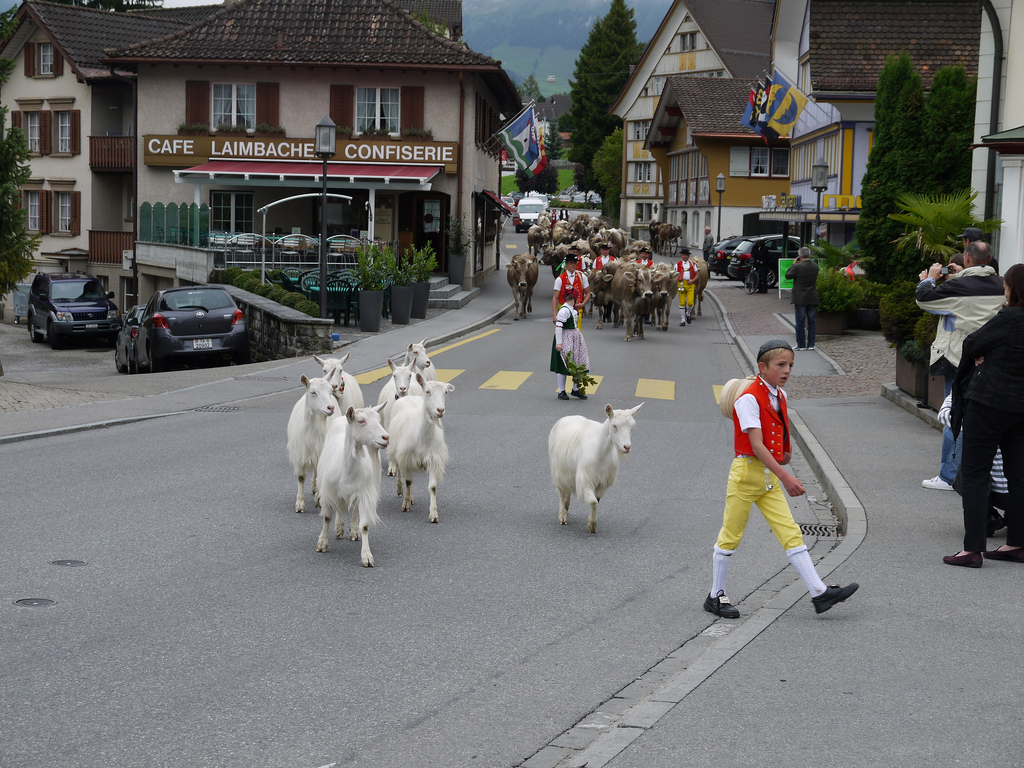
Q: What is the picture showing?
A: It is showing a street.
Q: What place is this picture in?
A: It is at the street.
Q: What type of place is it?
A: It is a street.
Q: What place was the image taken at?
A: It was taken at the street.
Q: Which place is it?
A: It is a street.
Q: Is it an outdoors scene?
A: Yes, it is outdoors.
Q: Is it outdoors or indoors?
A: It is outdoors.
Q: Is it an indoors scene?
A: No, it is outdoors.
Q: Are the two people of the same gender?
A: No, they are both male and female.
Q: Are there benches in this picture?
A: No, there are no benches.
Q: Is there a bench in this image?
A: No, there are no benches.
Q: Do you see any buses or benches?
A: No, there are no benches or buses.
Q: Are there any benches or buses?
A: No, there are no benches or buses.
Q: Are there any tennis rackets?
A: No, there are no tennis rackets.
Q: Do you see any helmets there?
A: No, there are no helmets.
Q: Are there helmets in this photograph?
A: No, there are no helmets.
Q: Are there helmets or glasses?
A: No, there are no helmets or glasses.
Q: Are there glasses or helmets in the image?
A: No, there are no helmets or glasses.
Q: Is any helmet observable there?
A: No, there are no helmets.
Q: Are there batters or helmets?
A: No, there are no helmets or batters.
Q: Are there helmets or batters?
A: No, there are no helmets or batters.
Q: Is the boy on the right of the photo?
A: Yes, the boy is on the right of the image.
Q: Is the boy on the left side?
A: No, the boy is on the right of the image.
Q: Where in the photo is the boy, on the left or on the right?
A: The boy is on the right of the image.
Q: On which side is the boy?
A: The boy is on the right of the image.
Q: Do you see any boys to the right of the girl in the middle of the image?
A: Yes, there is a boy to the right of the girl.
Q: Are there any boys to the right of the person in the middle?
A: Yes, there is a boy to the right of the girl.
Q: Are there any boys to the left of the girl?
A: No, the boy is to the right of the girl.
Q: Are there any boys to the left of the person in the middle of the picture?
A: No, the boy is to the right of the girl.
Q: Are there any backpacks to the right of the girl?
A: No, there is a boy to the right of the girl.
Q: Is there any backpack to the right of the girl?
A: No, there is a boy to the right of the girl.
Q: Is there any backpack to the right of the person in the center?
A: No, there is a boy to the right of the girl.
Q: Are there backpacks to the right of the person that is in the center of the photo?
A: No, there is a boy to the right of the girl.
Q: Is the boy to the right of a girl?
A: Yes, the boy is to the right of a girl.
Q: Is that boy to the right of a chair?
A: No, the boy is to the right of a girl.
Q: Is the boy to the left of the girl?
A: No, the boy is to the right of the girl.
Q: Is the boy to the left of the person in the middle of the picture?
A: No, the boy is to the right of the girl.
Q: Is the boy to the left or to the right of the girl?
A: The boy is to the right of the girl.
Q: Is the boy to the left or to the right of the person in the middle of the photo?
A: The boy is to the right of the girl.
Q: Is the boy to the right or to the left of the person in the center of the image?
A: The boy is to the right of the girl.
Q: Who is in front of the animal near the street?
A: The boy is in front of the animal.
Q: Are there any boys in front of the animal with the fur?
A: Yes, there is a boy in front of the animal.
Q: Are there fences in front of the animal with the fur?
A: No, there is a boy in front of the animal.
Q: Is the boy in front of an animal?
A: Yes, the boy is in front of an animal.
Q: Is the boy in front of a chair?
A: No, the boy is in front of an animal.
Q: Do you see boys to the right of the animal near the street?
A: Yes, there is a boy to the right of the animal.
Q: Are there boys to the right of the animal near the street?
A: Yes, there is a boy to the right of the animal.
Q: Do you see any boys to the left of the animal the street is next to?
A: No, the boy is to the right of the animal.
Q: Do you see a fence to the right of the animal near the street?
A: No, there is a boy to the right of the animal.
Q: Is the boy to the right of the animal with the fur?
A: Yes, the boy is to the right of the animal.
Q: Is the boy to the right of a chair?
A: No, the boy is to the right of the animal.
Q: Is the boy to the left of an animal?
A: No, the boy is to the right of an animal.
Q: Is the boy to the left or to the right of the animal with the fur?
A: The boy is to the right of the animal.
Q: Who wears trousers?
A: The boy wears trousers.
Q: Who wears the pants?
A: The boy wears trousers.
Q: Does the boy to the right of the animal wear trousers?
A: Yes, the boy wears trousers.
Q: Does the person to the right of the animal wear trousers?
A: Yes, the boy wears trousers.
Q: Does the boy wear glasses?
A: No, the boy wears trousers.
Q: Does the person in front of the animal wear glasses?
A: No, the boy wears trousers.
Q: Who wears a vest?
A: The boy wears a vest.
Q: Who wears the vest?
A: The boy wears a vest.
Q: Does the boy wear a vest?
A: Yes, the boy wears a vest.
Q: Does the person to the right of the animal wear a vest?
A: Yes, the boy wears a vest.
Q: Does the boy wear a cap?
A: No, the boy wears a vest.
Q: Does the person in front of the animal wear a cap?
A: No, the boy wears a vest.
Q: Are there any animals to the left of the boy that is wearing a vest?
A: Yes, there is an animal to the left of the boy.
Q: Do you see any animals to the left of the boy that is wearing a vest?
A: Yes, there is an animal to the left of the boy.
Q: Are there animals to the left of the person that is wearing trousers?
A: Yes, there is an animal to the left of the boy.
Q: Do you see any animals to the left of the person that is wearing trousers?
A: Yes, there is an animal to the left of the boy.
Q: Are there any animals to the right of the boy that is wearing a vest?
A: No, the animal is to the left of the boy.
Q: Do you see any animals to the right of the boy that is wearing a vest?
A: No, the animal is to the left of the boy.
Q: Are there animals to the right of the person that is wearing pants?
A: No, the animal is to the left of the boy.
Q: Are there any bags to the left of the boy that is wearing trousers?
A: No, there is an animal to the left of the boy.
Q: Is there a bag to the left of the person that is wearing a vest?
A: No, there is an animal to the left of the boy.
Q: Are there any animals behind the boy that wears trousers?
A: Yes, there is an animal behind the boy.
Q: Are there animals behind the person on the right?
A: Yes, there is an animal behind the boy.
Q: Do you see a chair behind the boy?
A: No, there is an animal behind the boy.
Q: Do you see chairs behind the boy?
A: No, there is an animal behind the boy.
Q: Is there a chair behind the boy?
A: No, there is an animal behind the boy.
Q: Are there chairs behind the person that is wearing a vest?
A: No, there is an animal behind the boy.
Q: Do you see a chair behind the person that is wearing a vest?
A: No, there is an animal behind the boy.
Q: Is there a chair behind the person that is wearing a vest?
A: No, there is an animal behind the boy.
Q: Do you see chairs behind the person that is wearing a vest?
A: No, there is an animal behind the boy.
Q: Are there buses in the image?
A: No, there are no buses.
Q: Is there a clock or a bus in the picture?
A: No, there are no buses or clocks.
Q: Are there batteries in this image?
A: No, there are no batteries.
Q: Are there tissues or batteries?
A: No, there are no batteries or tissues.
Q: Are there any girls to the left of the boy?
A: Yes, there is a girl to the left of the boy.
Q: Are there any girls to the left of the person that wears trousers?
A: Yes, there is a girl to the left of the boy.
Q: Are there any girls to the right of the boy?
A: No, the girl is to the left of the boy.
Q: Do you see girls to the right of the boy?
A: No, the girl is to the left of the boy.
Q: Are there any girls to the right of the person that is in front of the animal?
A: No, the girl is to the left of the boy.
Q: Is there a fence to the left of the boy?
A: No, there is a girl to the left of the boy.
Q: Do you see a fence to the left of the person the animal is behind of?
A: No, there is a girl to the left of the boy.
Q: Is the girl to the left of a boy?
A: Yes, the girl is to the left of a boy.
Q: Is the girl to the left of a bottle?
A: No, the girl is to the left of a boy.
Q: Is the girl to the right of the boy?
A: No, the girl is to the left of the boy.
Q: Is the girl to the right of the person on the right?
A: No, the girl is to the left of the boy.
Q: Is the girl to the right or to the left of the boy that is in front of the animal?
A: The girl is to the left of the boy.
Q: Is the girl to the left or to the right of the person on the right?
A: The girl is to the left of the boy.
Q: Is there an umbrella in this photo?
A: No, there are no umbrellas.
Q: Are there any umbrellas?
A: No, there are no umbrellas.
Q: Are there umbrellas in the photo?
A: No, there are no umbrellas.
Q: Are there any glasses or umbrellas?
A: No, there are no umbrellas or glasses.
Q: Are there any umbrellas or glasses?
A: No, there are no umbrellas or glasses.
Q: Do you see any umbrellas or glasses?
A: No, there are no umbrellas or glasses.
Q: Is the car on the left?
A: Yes, the car is on the left of the image.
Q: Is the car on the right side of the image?
A: No, the car is on the left of the image.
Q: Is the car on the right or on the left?
A: The car is on the left of the image.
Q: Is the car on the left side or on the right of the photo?
A: The car is on the left of the image.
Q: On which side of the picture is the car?
A: The car is on the left of the image.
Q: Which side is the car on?
A: The car is on the left of the image.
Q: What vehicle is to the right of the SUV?
A: The vehicle is a car.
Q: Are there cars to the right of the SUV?
A: Yes, there is a car to the right of the SUV.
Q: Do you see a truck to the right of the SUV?
A: No, there is a car to the right of the SUV.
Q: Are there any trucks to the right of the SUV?
A: No, there is a car to the right of the SUV.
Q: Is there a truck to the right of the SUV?
A: No, there is a car to the right of the SUV.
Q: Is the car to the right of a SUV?
A: Yes, the car is to the right of a SUV.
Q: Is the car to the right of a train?
A: No, the car is to the right of a SUV.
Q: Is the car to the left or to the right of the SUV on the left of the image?
A: The car is to the right of the SUV.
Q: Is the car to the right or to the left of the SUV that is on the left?
A: The car is to the right of the SUV.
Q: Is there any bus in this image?
A: No, there are no buses.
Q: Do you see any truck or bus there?
A: No, there are no buses or trucks.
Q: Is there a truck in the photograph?
A: No, there are no trucks.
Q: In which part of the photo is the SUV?
A: The SUV is on the left of the image.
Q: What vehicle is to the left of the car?
A: The vehicle is a SUV.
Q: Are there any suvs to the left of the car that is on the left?
A: Yes, there is a SUV to the left of the car.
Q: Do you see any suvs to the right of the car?
A: No, the SUV is to the left of the car.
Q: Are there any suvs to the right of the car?
A: No, the SUV is to the left of the car.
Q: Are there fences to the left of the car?
A: No, there is a SUV to the left of the car.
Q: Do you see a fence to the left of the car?
A: No, there is a SUV to the left of the car.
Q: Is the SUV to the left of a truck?
A: No, the SUV is to the left of the car.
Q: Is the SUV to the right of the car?
A: No, the SUV is to the left of the car.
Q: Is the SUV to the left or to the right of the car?
A: The SUV is to the left of the car.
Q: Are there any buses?
A: No, there are no buses.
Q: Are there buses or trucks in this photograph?
A: No, there are no buses or trucks.